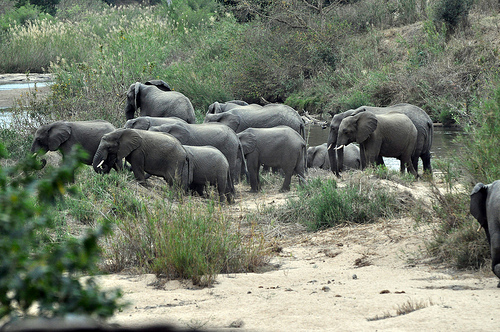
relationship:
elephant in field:
[334, 111, 421, 176] [2, 114, 500, 330]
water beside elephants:
[2, 107, 485, 174] [16, 75, 442, 207]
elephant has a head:
[334, 111, 421, 176] [338, 115, 373, 145]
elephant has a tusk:
[334, 111, 421, 176] [334, 143, 343, 152]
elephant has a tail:
[334, 111, 421, 176] [426, 120, 436, 155]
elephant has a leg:
[334, 111, 421, 176] [407, 153, 418, 179]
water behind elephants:
[2, 107, 485, 174] [16, 75, 442, 207]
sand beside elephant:
[168, 257, 451, 329] [334, 111, 421, 176]